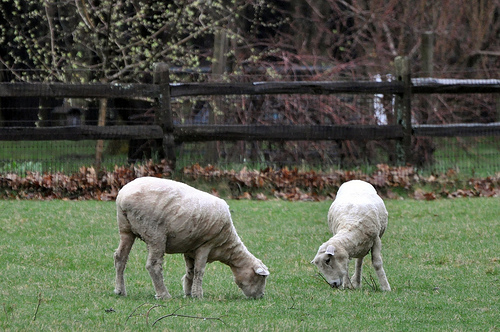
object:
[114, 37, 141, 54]
leaves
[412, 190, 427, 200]
leaves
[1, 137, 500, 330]
grass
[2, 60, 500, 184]
fence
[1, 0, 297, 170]
tree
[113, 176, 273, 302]
sheep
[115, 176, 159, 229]
rear end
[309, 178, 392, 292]
sheep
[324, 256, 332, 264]
eye